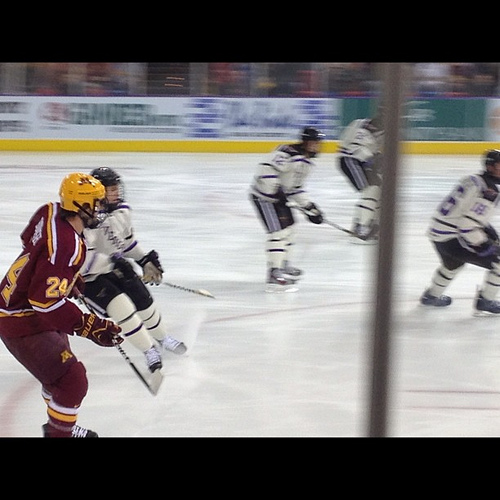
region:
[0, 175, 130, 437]
hockey player in marron and gold uniform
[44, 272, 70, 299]
number 24 on sleeve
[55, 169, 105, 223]
yellow helmet on hockey player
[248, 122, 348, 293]
hockey player in white and black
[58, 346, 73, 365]
M logo on pants leg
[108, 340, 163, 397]
hockey stick held by player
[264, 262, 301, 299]
black skates on player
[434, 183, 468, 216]
black number 6 on player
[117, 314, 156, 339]
black stripes on white socks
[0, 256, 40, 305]
number 4 on player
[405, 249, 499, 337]
hockey player skating on ice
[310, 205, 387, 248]
player holding a hockey stick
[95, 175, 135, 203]
helmet has a cage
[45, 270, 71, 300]
24 written on players jersey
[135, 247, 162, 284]
player wearing hockey gloves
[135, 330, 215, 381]
player wearing hockey skates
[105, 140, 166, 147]
yellow stripe along bottom of rink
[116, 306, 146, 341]
two blue stripes on the legs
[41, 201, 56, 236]
yellow and white stripes on jersey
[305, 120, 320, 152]
hockey helmet is black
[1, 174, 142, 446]
Red, white, yellow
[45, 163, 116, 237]
Has a yellow helmet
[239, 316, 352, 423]
White floor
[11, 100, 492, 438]
hockey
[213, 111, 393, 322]
White and black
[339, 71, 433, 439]
A pole right here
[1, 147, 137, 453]
Only one member of the opposite team in shot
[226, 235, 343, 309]
Ice skates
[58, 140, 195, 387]
He is skating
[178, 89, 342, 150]
Logos on the white gate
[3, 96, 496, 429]
men playing hockey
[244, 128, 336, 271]
black and white hockey uniform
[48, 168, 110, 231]
yellow helmet with black straps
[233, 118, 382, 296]
man slightly hunched over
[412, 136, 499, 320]
player skating on the ice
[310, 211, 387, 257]
hockey stick lifted in the air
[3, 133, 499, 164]
yellow strip around the edge of the arena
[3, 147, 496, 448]
ice rink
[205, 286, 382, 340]
thin scratch on the ice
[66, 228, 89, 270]
white and yellow stripes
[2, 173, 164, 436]
hockey player in red and gold jersey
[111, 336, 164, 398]
white and black hockey stick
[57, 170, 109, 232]
yellow helmet on head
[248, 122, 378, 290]
hockey player in white and blue uniform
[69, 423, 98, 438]
white laces on black ice skates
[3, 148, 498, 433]
ice skating rink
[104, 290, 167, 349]
white shin guards with black stripes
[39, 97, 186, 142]
green lettering on white backboard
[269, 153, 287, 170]
blue number 12 on white jersey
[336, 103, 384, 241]
player skating on ice